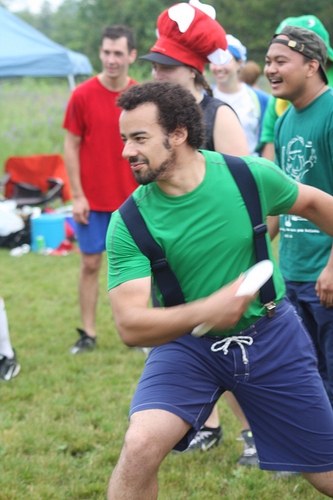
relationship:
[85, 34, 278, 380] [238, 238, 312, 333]
man holding frisbee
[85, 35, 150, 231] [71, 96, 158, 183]
man in red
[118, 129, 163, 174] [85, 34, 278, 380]
nose of man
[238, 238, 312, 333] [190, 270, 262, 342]
frisbee in hand